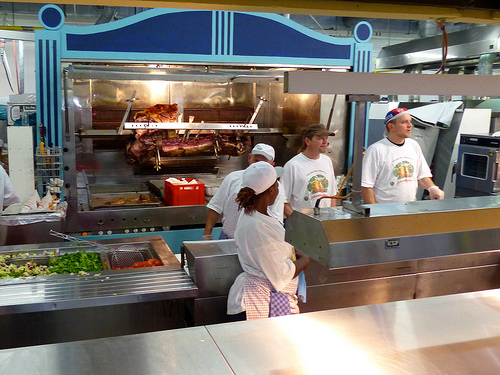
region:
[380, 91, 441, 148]
the head of a man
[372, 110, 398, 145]
the ear of a man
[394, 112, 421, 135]
the eyes of a man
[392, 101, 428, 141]
the nose of a man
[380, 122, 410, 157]
the neck of a man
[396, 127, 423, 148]
the chin of a man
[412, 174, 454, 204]
the hand of a man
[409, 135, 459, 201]
the arm of a man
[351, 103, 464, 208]
the body of a man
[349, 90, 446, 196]
a man wearing a shirt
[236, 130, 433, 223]
People cooking in the kitchen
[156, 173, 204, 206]
A red crate on the tble.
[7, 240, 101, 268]
Lettuce in the pan.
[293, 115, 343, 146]
The man is wearing a cap.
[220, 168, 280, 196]
The lady is wearing a white cap.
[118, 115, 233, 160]
Meat cooking on the grill.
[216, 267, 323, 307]
The lady is wearing an apron.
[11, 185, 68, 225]
Garbage in the bin.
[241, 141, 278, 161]
The man is wearing a white cap.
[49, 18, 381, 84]
Top of the ceiling is blue.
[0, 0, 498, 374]
the interior of a restaurant kitchen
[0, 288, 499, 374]
a large metal kitchen surface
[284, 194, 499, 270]
a large metal lamp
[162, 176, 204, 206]
a red crate in the background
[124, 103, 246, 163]
a large piece of meat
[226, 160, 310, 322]
a kitchen worker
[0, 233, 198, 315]
a metal preparation table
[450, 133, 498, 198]
an oven in the background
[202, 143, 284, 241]
kitchen worker with a white t-shirt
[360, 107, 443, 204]
kitchen worker wearing a cap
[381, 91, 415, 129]
Person wearing hat on head.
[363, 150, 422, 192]
Person wearing white t-shirt.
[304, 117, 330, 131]
Person wearing hat on head.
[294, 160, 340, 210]
Person wearing white t-shirt.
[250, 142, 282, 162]
Person wearing hat on head.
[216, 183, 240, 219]
Person wearing white t-shirt.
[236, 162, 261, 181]
Person wearing hat on head.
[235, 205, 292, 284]
Person wearing white t-shirt.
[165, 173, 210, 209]
Red crate behind people.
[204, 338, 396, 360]
Stainless steel counter top.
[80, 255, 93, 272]
food in the compartment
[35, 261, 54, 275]
food in the compartment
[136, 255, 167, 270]
food in the compartment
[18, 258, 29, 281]
food in the compartment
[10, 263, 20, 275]
food in the compartment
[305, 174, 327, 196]
design on the shirt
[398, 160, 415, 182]
design on the shirt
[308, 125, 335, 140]
hat on the shirt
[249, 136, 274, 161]
hat on the person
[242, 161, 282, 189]
hat on the person